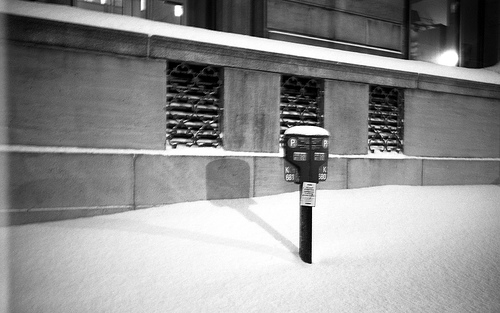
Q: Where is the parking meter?
A: In the street.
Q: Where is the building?
A: Behind the parking meter.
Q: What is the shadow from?
A: The parking meter.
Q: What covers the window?
A: A curtain.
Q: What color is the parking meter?
A: Black.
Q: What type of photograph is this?
A: Black and white.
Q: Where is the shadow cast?
A: On the snow.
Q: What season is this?
A: Winter.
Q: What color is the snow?
A: White.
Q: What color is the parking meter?
A: Black.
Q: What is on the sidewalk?
A: A parking meter.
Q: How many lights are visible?
A: Four.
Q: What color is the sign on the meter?
A: White.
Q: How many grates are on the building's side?
A: Three.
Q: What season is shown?
A: Winter.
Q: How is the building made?
A: Of stone.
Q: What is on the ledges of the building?
A: Snow.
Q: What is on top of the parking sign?
A: Snow.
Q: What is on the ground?
A: Snow.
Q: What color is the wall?
A: Gray.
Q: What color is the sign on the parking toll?
A: White.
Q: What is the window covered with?
A: Iron bars.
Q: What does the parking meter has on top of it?
A: Snow.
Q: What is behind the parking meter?
A: Building.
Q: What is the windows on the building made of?
A: Iron.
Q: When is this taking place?
A: Winter.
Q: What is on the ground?
A: Snow.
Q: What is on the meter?
A: A sign.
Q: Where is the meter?
A: Sidewalk.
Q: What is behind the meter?
A: A building.